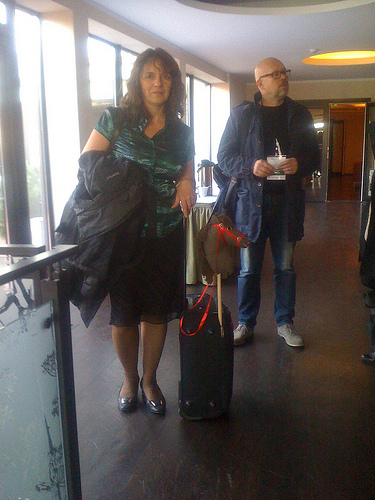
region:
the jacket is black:
[54, 152, 150, 322]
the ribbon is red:
[180, 285, 217, 339]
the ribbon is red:
[169, 269, 231, 364]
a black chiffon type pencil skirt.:
[104, 209, 190, 324]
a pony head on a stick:
[199, 213, 254, 319]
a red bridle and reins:
[170, 216, 242, 336]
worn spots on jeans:
[242, 235, 293, 275]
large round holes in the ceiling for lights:
[304, 46, 374, 66]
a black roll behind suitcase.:
[178, 291, 234, 423]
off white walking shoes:
[230, 321, 303, 353]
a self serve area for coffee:
[197, 155, 212, 197]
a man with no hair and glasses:
[219, 54, 320, 346]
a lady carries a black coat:
[58, 151, 149, 326]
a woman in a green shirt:
[60, 44, 198, 417]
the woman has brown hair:
[119, 46, 185, 126]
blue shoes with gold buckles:
[113, 374, 169, 415]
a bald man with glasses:
[216, 56, 319, 348]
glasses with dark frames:
[254, 67, 292, 79]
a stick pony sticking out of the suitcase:
[178, 211, 251, 422]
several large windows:
[0, 2, 214, 229]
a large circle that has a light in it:
[300, 48, 374, 64]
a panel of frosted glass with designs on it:
[1, 301, 72, 498]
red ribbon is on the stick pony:
[178, 220, 246, 337]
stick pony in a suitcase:
[176, 206, 245, 421]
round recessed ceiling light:
[299, 43, 374, 68]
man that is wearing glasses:
[208, 50, 323, 348]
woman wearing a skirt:
[80, 40, 199, 416]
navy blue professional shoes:
[115, 378, 166, 415]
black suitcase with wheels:
[176, 286, 235, 425]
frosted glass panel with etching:
[0, 302, 71, 498]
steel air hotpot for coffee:
[196, 157, 214, 197]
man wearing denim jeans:
[211, 53, 321, 346]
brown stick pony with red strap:
[177, 212, 250, 337]